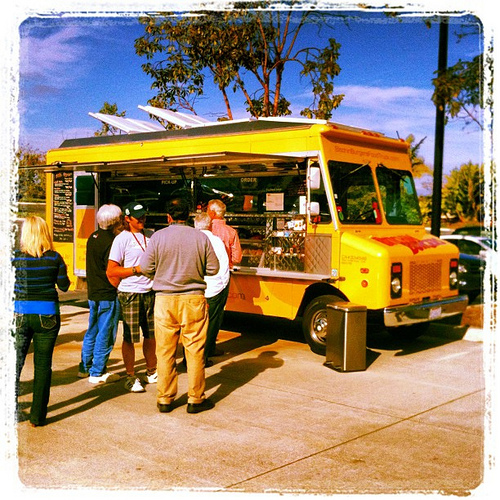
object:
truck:
[43, 101, 471, 356]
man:
[140, 197, 223, 415]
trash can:
[318, 293, 371, 374]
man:
[105, 202, 158, 395]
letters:
[376, 223, 444, 257]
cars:
[440, 230, 500, 266]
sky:
[13, 14, 486, 198]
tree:
[430, 50, 486, 127]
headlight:
[387, 274, 405, 296]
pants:
[152, 290, 211, 411]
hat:
[126, 197, 150, 224]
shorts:
[118, 290, 156, 344]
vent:
[134, 89, 211, 130]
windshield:
[326, 157, 384, 225]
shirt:
[140, 223, 223, 293]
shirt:
[108, 232, 152, 297]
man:
[77, 203, 124, 387]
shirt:
[82, 231, 120, 305]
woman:
[17, 210, 72, 427]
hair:
[18, 216, 58, 260]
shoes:
[155, 395, 173, 416]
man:
[195, 199, 242, 279]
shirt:
[209, 217, 245, 272]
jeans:
[13, 317, 64, 425]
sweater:
[13, 251, 74, 315]